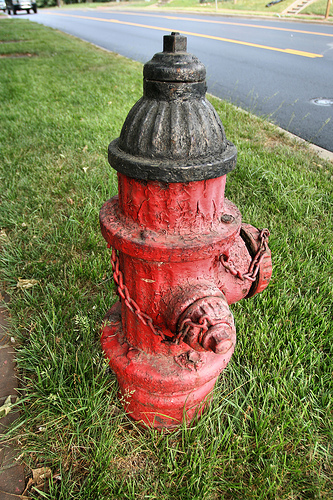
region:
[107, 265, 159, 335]
slightly rusted red painted linked chain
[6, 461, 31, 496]
splotch of speckled dirt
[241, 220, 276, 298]
two inch diameter hydrant cap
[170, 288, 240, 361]
one inch diameter hydrant cap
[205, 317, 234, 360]
weathered red painted hex flange nut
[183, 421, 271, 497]
short vibrant green grass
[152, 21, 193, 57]
black painted square metal nut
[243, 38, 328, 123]
black asphalt paved street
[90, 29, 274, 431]
red and black painted fire hydrant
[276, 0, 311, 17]
cement steps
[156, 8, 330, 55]
The median of the road.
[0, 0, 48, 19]
Two cars are on the road.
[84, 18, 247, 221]
The top of the hydrant is black.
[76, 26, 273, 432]
The hydrant is black and red.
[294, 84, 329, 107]
A utility access is on the road.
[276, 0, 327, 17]
Stairs can be seen in the background.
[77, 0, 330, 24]
A sidewalk runs along the road.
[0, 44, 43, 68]
Holes in the grass.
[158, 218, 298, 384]
The hydrant is sealed tight.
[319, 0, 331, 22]
A utility pole is on the side of the road.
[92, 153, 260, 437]
old red fire hydrant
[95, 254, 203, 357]
red chaino on hydrant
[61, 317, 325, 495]
grass is recently mowed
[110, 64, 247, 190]
hydrant has black top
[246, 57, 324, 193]
recently paved blacktop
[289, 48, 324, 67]
recently painted street lines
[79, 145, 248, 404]
hydrant is rusty and peeling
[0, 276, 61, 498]
leaves are on the ground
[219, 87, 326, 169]
curb at the grass edge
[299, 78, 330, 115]
metal drain cover in street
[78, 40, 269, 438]
The fire hydrant is red and black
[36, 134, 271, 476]
The fire hydrant is surrounded by grass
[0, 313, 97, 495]
Cement is next to the grass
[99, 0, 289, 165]
The grass is on either side of the street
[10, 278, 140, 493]
There are brown leaves on the cement and grass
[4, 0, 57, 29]
A black car drives on the street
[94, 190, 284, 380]
The fire hydrant has a red chain connecting its valves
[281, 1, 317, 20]
Grey steps lead up a grassy hill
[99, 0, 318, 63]
The street is divided by yellow lines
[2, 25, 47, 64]
There are two holes in the grass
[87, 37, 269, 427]
a fire hydrant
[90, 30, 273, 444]
a fire hydrant in the grass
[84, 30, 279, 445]
the fire hydrant is red and black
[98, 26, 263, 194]
the top of the fire hydrant is black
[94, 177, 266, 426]
the chains on the hydrant are painted red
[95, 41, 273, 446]
the paint on the hydrant is in poor repair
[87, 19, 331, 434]
the fire hydrant is beside the road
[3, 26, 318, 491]
the grass is green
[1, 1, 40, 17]
two cars are on the road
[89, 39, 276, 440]
the fire hydrant is not open